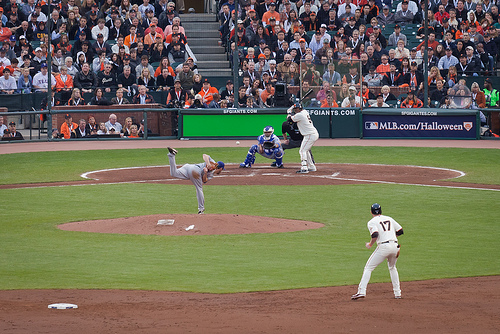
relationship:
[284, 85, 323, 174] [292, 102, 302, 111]
batter wearing helmet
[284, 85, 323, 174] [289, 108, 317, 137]
batter wearing shirt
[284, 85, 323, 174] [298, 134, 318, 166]
batter wearing pants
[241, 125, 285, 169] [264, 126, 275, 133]
catcher wearing helmet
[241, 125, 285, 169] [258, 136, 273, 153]
catcher wearing chest guard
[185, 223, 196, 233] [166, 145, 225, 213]
rosin bag behind pitcher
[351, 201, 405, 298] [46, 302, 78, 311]
player near second base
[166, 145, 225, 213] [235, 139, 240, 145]
pitcher pitching baseball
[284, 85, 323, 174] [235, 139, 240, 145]
batter ready to hit baseball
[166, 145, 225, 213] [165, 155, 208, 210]
pitcher wearing pants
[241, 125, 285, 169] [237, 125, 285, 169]
catcher wearing equipment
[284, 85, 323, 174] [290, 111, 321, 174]
batter wearing uniform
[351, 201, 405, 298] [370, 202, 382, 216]
player wearing helmet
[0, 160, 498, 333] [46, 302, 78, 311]
infield dirt around second base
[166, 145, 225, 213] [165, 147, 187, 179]
pitcher has leg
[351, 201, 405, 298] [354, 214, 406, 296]
player wearing uniform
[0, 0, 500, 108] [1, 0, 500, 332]
crowd inside stadium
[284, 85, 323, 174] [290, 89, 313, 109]
batter raising bat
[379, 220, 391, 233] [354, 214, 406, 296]
number printed on uniform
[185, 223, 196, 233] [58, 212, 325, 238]
rosin bag on top of pitching mound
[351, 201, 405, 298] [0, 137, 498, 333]
player standing on field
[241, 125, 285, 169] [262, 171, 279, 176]
catcher kneeling behind home plate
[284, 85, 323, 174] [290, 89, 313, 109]
batter ready to swing bat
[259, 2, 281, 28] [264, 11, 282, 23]
person wearing shirt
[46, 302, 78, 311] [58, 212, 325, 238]
second base behind pitching mound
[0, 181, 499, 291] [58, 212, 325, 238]
infield grass surround pitching mound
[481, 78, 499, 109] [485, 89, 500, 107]
person wearing shirt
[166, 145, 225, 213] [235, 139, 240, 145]
pitcher throwing baseball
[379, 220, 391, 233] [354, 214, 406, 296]
number screened onto uniform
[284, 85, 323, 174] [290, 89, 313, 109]
batter holding bat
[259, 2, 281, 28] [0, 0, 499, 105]
person sitting in bleachers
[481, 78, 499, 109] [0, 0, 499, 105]
person sitting in bleachers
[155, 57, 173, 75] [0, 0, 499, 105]
person sitting in bleachers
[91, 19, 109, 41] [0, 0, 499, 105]
person sitting in bleachers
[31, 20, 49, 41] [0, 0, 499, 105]
person sitting in bleachers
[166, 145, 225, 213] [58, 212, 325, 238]
pitcher standing on pitching mound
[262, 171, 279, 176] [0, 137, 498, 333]
home plate on surface of field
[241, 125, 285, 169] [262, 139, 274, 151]
catcher wearing catcher's mitt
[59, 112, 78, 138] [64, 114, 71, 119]
man wearing cap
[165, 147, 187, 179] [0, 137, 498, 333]
leg raised above field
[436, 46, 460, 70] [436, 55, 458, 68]
man wearing shirt